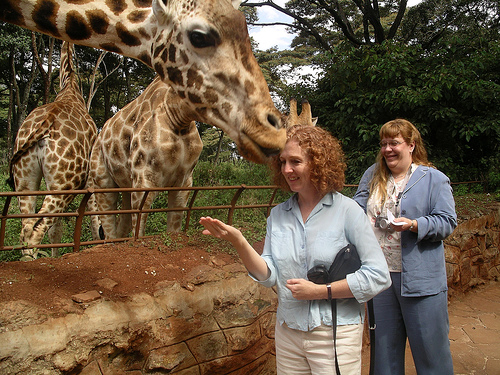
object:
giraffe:
[11, 0, 288, 262]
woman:
[200, 126, 391, 375]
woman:
[352, 118, 457, 375]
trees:
[4, 3, 497, 193]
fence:
[4, 174, 360, 251]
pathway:
[450, 273, 500, 373]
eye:
[291, 155, 299, 163]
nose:
[284, 163, 294, 173]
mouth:
[288, 175, 301, 183]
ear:
[408, 136, 414, 152]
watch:
[326, 280, 332, 301]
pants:
[273, 325, 365, 373]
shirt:
[248, 190, 391, 329]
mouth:
[232, 128, 281, 166]